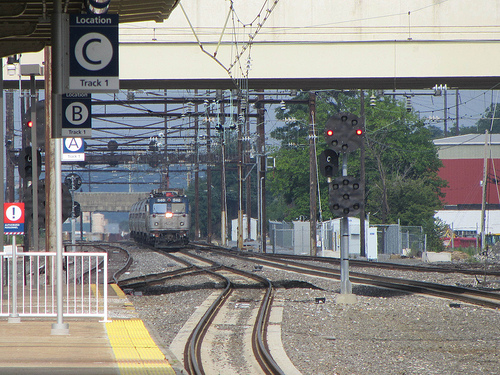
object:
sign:
[67, 9, 119, 93]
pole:
[50, 2, 72, 331]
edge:
[103, 280, 180, 374]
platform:
[4, 280, 174, 374]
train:
[128, 190, 193, 251]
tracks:
[188, 237, 500, 310]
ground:
[3, 235, 500, 374]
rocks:
[281, 273, 498, 373]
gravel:
[189, 240, 500, 315]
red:
[4, 201, 32, 226]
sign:
[4, 200, 28, 225]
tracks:
[158, 250, 294, 374]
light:
[26, 118, 33, 127]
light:
[355, 128, 365, 137]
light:
[327, 127, 337, 137]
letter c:
[78, 33, 109, 68]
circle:
[68, 102, 84, 126]